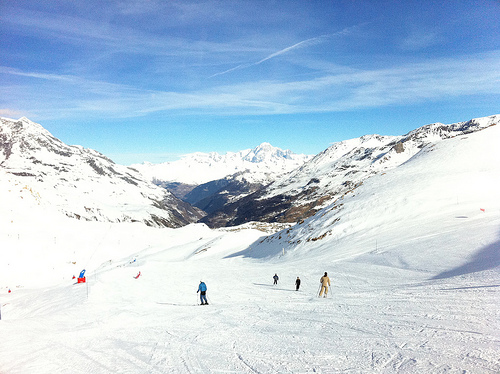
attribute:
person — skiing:
[186, 281, 213, 310]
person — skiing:
[264, 267, 282, 293]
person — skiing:
[291, 270, 304, 294]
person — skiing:
[312, 268, 337, 303]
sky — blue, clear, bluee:
[2, 0, 497, 162]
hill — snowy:
[0, 112, 203, 226]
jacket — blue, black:
[199, 283, 207, 292]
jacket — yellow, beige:
[320, 274, 330, 284]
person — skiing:
[195, 281, 211, 306]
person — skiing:
[294, 277, 302, 293]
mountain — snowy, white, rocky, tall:
[2, 116, 499, 249]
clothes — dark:
[295, 279, 302, 289]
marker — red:
[78, 274, 84, 283]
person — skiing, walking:
[318, 273, 332, 297]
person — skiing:
[273, 273, 280, 286]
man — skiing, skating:
[273, 275, 278, 281]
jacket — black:
[294, 279, 303, 286]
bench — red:
[75, 275, 89, 285]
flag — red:
[74, 271, 85, 284]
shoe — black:
[199, 298, 206, 306]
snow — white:
[1, 103, 497, 372]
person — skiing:
[272, 268, 280, 284]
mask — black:
[324, 270, 329, 276]